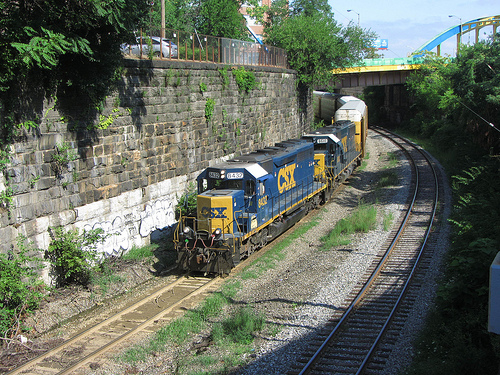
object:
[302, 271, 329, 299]
gravel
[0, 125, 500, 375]
ground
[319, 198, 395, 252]
weeds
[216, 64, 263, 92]
plants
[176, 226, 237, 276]
cattle guard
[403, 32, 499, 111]
leafy trees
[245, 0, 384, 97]
leafy trees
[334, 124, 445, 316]
railroad track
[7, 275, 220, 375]
tracks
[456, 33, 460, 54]
light pole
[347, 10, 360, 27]
light pole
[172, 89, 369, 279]
train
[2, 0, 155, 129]
green tree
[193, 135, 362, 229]
blue train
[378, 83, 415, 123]
tunnel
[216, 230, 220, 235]
lights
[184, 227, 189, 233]
lights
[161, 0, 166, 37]
pole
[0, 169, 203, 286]
graffiti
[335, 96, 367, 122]
roof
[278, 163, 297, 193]
csx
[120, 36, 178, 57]
car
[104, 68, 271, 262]
rocks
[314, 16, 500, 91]
bridge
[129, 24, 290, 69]
fence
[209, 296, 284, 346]
grass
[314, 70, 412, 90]
concrete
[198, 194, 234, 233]
nose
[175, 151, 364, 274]
engine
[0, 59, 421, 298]
wall